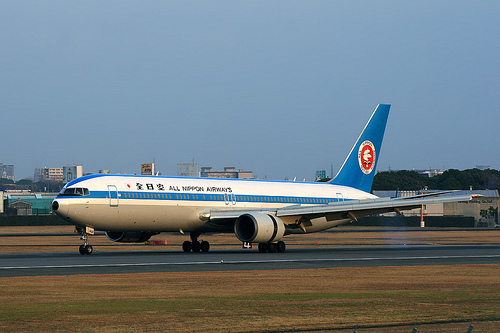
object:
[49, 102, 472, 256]
plane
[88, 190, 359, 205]
stripe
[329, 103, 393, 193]
tail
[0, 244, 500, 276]
runway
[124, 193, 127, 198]
windows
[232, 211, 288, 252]
engine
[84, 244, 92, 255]
wheels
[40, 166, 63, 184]
buildings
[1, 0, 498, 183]
sky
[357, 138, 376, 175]
emblem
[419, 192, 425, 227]
pole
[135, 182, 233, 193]
name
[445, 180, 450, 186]
trees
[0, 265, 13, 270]
markings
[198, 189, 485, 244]
wing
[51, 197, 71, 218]
tip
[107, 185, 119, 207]
door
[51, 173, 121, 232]
cockpit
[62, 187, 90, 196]
window